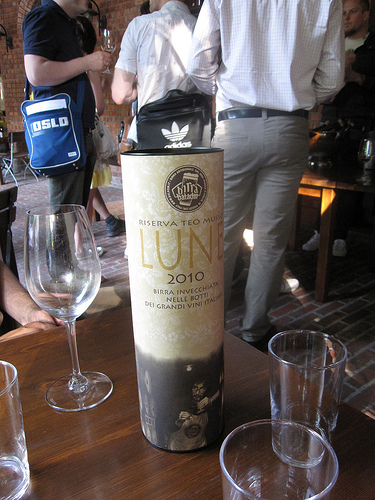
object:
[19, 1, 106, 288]
man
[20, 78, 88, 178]
blue bag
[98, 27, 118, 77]
wine glass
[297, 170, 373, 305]
table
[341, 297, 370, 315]
tiles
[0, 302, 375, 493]
table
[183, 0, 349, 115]
shirt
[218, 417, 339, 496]
glass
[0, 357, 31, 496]
glass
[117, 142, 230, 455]
wine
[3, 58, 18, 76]
bricks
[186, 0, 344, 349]
person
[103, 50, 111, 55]
bear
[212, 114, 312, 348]
gray pants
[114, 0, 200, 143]
shirt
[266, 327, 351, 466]
glass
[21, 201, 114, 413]
glass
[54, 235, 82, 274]
water spots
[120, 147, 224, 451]
wine bottle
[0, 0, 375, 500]
event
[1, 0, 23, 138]
walls